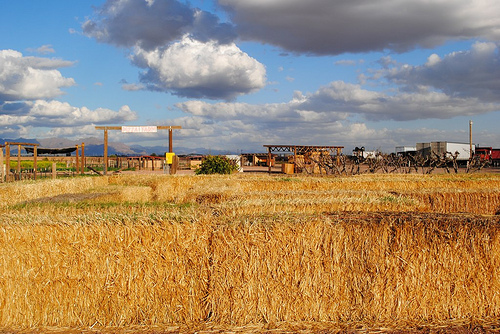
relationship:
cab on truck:
[462, 136, 498, 161] [464, 131, 499, 174]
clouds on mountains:
[79, 1, 271, 108] [22, 143, 277, 171]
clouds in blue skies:
[122, 35, 269, 103] [0, 1, 500, 153]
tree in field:
[194, 150, 239, 177] [49, 198, 477, 310]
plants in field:
[4, 140, 196, 210] [0, 152, 497, 329]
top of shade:
[267, 143, 345, 150] [264, 142, 344, 175]